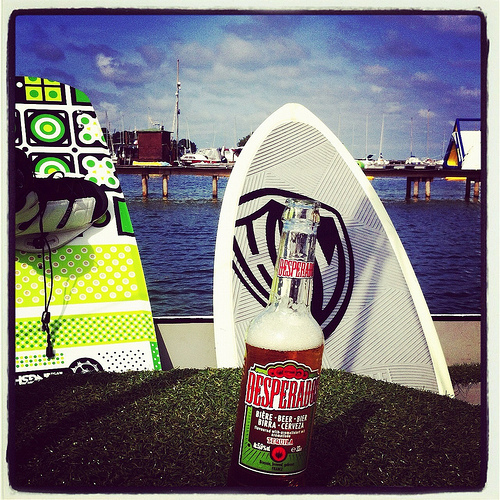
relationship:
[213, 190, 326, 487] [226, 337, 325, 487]
bottle has tequila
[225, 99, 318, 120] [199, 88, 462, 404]
edge of surfboard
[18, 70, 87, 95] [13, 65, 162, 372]
edge of surfboard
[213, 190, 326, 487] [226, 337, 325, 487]
bottle has beer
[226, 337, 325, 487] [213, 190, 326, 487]
beer in a bottle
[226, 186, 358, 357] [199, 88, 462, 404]
logo on surfboard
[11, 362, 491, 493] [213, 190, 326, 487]
grass under bottle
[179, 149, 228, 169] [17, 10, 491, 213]
boat in distance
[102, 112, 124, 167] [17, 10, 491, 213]
boat in distance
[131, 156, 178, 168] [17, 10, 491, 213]
boat in distance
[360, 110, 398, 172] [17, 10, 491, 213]
boat in distance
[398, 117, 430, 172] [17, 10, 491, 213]
boat in distance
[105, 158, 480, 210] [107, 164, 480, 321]
pier in water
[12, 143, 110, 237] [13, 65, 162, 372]
sneaker on a surfboard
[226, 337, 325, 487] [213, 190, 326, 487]
tequila in a bottle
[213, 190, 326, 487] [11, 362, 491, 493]
bottle on grass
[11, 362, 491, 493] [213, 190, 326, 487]
grass with a bottle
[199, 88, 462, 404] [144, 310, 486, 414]
surfboard leaning against wall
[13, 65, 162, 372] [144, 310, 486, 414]
surfboard leaning against wall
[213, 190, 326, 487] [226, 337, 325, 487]
bottle of tequila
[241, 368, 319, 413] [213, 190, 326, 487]
label on bottle